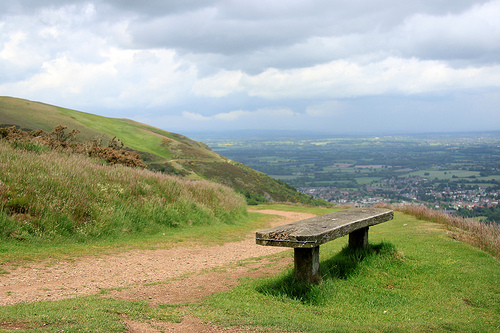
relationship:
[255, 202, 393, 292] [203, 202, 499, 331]
bench on grass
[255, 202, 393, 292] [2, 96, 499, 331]
bench in field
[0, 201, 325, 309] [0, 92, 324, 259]
road on hillside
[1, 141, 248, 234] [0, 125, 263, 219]
grass covering hillside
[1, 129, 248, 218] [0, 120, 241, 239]
grass covering hillside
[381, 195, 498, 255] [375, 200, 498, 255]
grass covering hillside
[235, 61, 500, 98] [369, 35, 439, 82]
cloud on sky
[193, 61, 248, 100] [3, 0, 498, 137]
cloud on sky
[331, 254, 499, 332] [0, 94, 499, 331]
grass on ground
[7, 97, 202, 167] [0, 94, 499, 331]
grass on ground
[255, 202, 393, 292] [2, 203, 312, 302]
bench on path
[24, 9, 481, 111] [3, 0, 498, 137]
clouds in sky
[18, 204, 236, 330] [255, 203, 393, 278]
path in front of bench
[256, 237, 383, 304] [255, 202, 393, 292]
shadow cast under bench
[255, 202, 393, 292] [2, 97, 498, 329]
bench in grass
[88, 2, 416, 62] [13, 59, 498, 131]
dark clouds cover sky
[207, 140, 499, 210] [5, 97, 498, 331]
town below hill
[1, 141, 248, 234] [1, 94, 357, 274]
grass covers hill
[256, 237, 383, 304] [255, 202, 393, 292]
shadow under bench